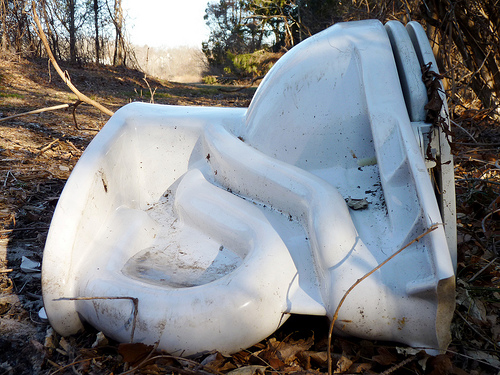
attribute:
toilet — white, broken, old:
[42, 14, 451, 351]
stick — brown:
[24, 20, 90, 121]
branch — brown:
[55, 320, 179, 374]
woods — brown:
[19, 13, 251, 92]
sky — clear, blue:
[142, 4, 197, 38]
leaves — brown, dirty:
[284, 337, 374, 374]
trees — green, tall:
[208, 5, 300, 46]